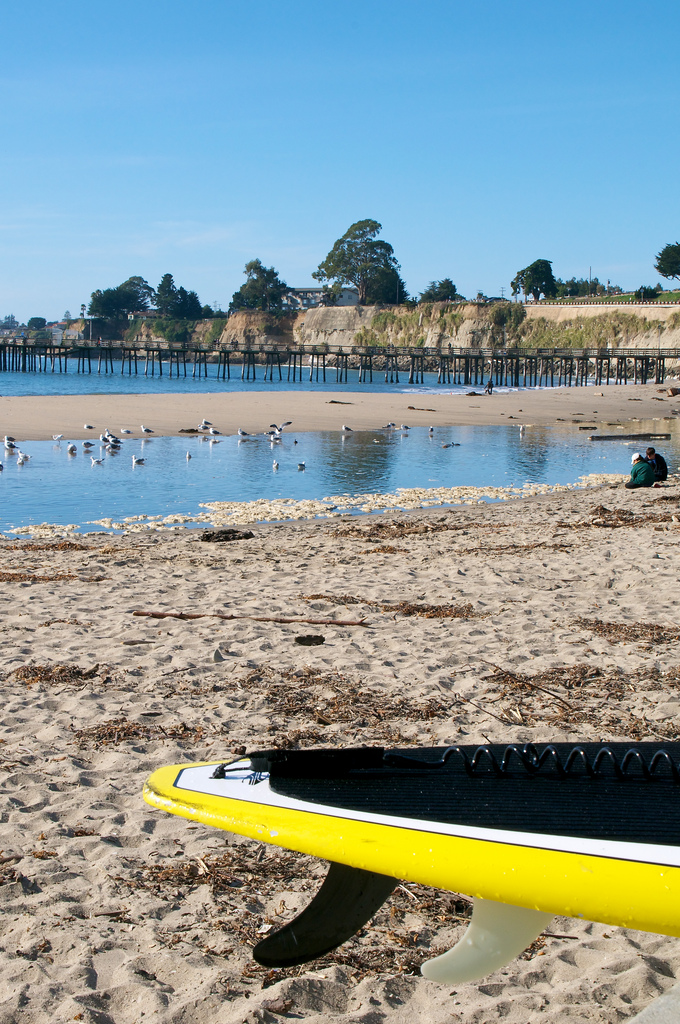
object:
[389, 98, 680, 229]
sky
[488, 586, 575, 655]
sand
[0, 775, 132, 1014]
sand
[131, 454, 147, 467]
bird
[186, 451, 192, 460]
bird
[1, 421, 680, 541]
pond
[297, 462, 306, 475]
bird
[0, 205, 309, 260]
clouds